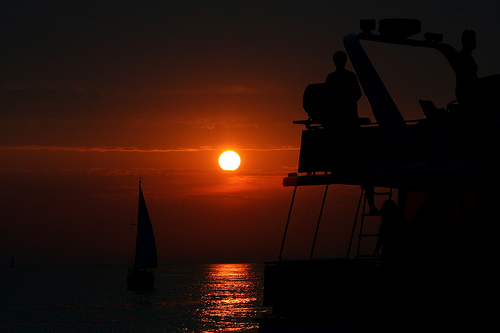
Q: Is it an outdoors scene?
A: Yes, it is outdoors.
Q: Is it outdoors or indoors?
A: It is outdoors.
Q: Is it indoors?
A: No, it is outdoors.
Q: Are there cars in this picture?
A: No, there are no cars.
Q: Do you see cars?
A: No, there are no cars.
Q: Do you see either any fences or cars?
A: No, there are no cars or fences.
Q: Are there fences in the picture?
A: No, there are no fences.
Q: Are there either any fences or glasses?
A: No, there are no fences or glasses.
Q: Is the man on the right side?
A: Yes, the man is on the right of the image.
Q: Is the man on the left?
A: No, the man is on the right of the image.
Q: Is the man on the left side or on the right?
A: The man is on the right of the image.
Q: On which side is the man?
A: The man is on the right of the image.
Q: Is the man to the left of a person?
A: Yes, the man is to the left of a person.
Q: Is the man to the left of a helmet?
A: No, the man is to the left of a person.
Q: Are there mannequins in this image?
A: No, there are no mannequins.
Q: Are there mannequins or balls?
A: No, there are no mannequins or balls.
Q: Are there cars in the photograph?
A: No, there are no cars.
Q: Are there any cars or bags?
A: No, there are no cars or bags.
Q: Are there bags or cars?
A: No, there are no cars or bags.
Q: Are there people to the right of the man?
A: Yes, there is a person to the right of the man.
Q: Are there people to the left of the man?
A: No, the person is to the right of the man.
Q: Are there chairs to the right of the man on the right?
A: No, there is a person to the right of the man.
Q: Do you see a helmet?
A: No, there are no helmets.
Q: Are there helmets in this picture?
A: No, there are no helmets.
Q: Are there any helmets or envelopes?
A: No, there are no helmets or envelopes.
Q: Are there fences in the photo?
A: No, there are no fences.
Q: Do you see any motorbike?
A: No, there are no motorcycles.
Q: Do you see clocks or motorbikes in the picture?
A: No, there are no motorbikes or clocks.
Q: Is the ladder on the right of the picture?
A: Yes, the ladder is on the right of the image.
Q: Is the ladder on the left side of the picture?
A: No, the ladder is on the right of the image.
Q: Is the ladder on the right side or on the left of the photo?
A: The ladder is on the right of the image.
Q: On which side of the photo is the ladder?
A: The ladder is on the right of the image.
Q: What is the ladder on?
A: The ladder is on the boat.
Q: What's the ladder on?
A: The ladder is on the boat.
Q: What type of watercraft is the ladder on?
A: The ladder is on the boat.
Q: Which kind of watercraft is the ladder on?
A: The ladder is on the boat.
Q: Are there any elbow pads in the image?
A: No, there are no elbow pads.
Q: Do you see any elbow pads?
A: No, there are no elbow pads.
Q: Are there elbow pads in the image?
A: No, there are no elbow pads.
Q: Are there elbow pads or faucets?
A: No, there are no elbow pads or faucets.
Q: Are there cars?
A: No, there are no cars.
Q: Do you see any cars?
A: No, there are no cars.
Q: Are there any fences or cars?
A: No, there are no cars or fences.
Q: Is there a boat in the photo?
A: Yes, there is a boat.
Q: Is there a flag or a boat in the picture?
A: Yes, there is a boat.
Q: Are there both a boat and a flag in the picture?
A: No, there is a boat but no flags.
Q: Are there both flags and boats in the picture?
A: No, there is a boat but no flags.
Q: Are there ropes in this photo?
A: No, there are no ropes.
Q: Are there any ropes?
A: No, there are no ropes.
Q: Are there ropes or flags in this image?
A: No, there are no ropes or flags.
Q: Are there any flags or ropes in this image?
A: No, there are no ropes or flags.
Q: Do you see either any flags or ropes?
A: No, there are no ropes or flags.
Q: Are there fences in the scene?
A: No, there are no fences.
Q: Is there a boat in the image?
A: Yes, there is a boat.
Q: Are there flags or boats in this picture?
A: Yes, there is a boat.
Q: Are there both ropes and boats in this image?
A: No, there is a boat but no ropes.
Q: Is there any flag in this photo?
A: No, there are no flags.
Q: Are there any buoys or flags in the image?
A: No, there are no flags or buoys.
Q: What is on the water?
A: The boat is on the water.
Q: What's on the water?
A: The boat is on the water.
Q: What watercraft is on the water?
A: The watercraft is a boat.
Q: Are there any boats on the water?
A: Yes, there is a boat on the water.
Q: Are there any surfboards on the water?
A: No, there is a boat on the water.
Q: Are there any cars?
A: No, there are no cars.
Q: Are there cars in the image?
A: No, there are no cars.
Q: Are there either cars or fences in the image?
A: No, there are no cars or fences.